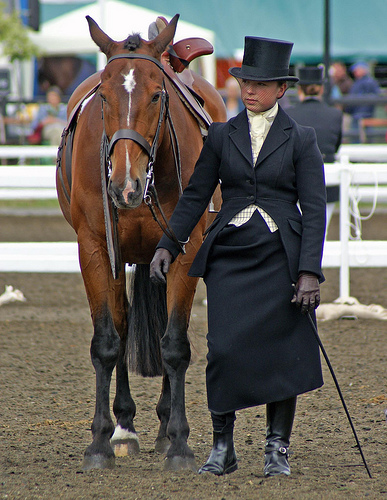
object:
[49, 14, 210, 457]
horse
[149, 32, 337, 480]
woman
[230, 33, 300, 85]
hat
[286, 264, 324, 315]
gloves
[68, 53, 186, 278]
reigns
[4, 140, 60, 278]
fence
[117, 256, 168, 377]
tail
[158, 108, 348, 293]
coat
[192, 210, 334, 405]
skirt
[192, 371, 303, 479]
boots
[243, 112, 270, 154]
shirt